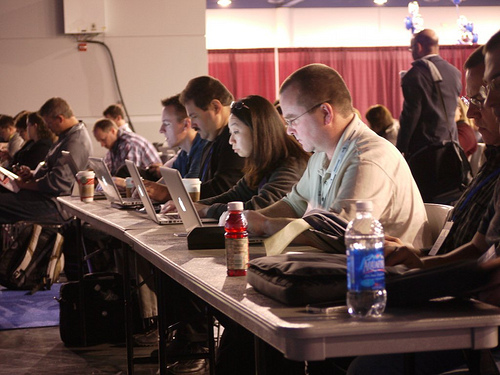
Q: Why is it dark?
A: Dim lighting.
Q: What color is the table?
A: Grey.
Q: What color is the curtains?
A: Red.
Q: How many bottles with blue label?
A: One.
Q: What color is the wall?
A: White.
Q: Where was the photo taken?
A: In computer class.